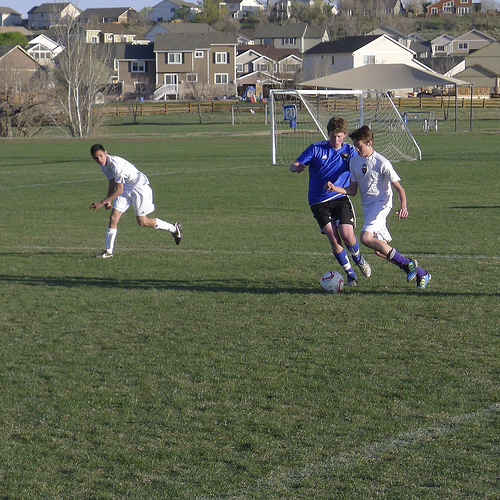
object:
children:
[89, 143, 183, 260]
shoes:
[415, 260, 432, 290]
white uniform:
[348, 152, 402, 246]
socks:
[386, 247, 410, 266]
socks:
[416, 266, 427, 276]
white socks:
[105, 227, 118, 254]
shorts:
[361, 205, 393, 244]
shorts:
[109, 184, 157, 217]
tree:
[16, 20, 121, 138]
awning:
[296, 62, 461, 132]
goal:
[267, 88, 421, 168]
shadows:
[0, 274, 255, 283]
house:
[427, 0, 475, 22]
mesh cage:
[274, 90, 417, 162]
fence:
[96, 96, 500, 116]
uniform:
[101, 151, 156, 219]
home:
[148, 31, 238, 103]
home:
[302, 34, 415, 82]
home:
[0, 42, 46, 91]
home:
[443, 27, 498, 56]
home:
[248, 23, 331, 50]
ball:
[319, 270, 344, 294]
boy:
[288, 117, 372, 288]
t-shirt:
[295, 140, 357, 206]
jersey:
[295, 139, 358, 206]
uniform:
[295, 139, 356, 235]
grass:
[0, 113, 500, 500]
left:
[0, 1, 211, 497]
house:
[149, 31, 239, 103]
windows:
[214, 51, 227, 65]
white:
[100, 154, 154, 217]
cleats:
[172, 221, 183, 246]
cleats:
[94, 250, 114, 258]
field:
[0, 115, 499, 500]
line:
[220, 401, 500, 500]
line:
[0, 245, 499, 259]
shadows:
[52, 279, 499, 298]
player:
[325, 123, 432, 290]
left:
[94, 249, 114, 260]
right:
[428, 0, 500, 500]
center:
[0, 129, 500, 500]